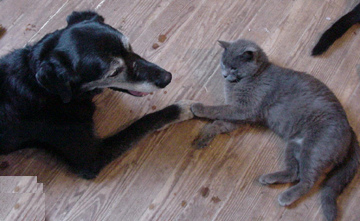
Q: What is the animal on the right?
A: A cat.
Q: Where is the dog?
A: On the left.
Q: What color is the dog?
A: Black.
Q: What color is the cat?
A: Grey.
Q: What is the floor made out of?
A: Wood.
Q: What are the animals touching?
A: Paws.